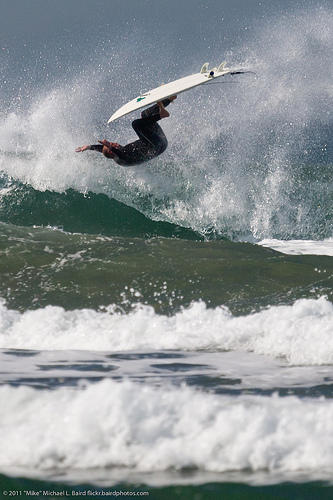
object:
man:
[75, 94, 178, 167]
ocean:
[0, 0, 332, 498]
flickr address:
[87, 489, 150, 497]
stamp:
[8, 489, 23, 497]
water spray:
[1, 3, 332, 246]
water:
[0, 0, 333, 500]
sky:
[0, 1, 332, 168]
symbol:
[0, 489, 11, 498]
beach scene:
[0, 0, 332, 489]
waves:
[0, 375, 333, 476]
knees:
[131, 119, 136, 131]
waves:
[0, 293, 332, 368]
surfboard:
[107, 60, 259, 125]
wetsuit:
[88, 97, 173, 167]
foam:
[0, 346, 333, 403]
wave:
[0, 1, 333, 238]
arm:
[97, 139, 128, 160]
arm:
[74, 144, 104, 153]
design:
[136, 92, 151, 102]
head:
[102, 145, 116, 159]